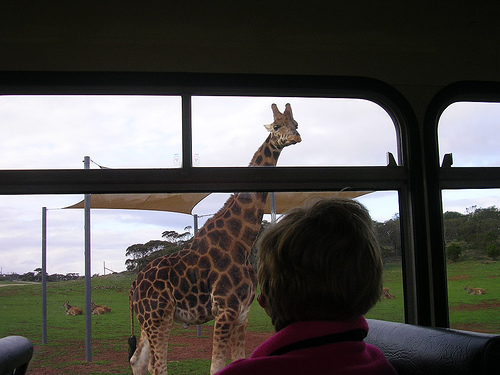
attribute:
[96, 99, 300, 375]
giraffe — standing, laying, looking, tall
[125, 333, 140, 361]
tail — log, black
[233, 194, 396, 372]
person — watchig, looking, sitting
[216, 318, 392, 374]
sweater — pink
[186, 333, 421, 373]
jacket — red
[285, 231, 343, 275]
hair — brown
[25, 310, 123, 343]
grass — laig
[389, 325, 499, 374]
seat — bech, black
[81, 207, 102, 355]
post — silver, metal